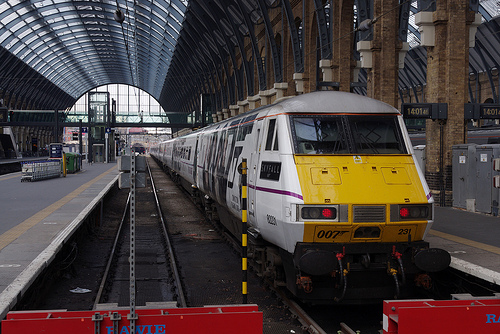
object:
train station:
[1, 1, 498, 332]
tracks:
[90, 156, 189, 311]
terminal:
[1, 127, 125, 317]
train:
[148, 91, 452, 305]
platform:
[1, 161, 119, 314]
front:
[282, 89, 436, 254]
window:
[289, 114, 353, 158]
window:
[347, 113, 409, 157]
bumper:
[2, 302, 265, 333]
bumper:
[383, 292, 499, 333]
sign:
[402, 105, 432, 118]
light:
[321, 207, 332, 219]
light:
[399, 206, 410, 218]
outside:
[62, 84, 172, 157]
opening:
[63, 85, 173, 155]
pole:
[241, 160, 249, 303]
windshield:
[288, 112, 408, 154]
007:
[316, 230, 341, 240]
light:
[113, 9, 126, 22]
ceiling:
[1, 0, 424, 122]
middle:
[1, 0, 190, 102]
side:
[147, 107, 306, 256]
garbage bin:
[64, 151, 74, 173]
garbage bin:
[76, 153, 81, 172]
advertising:
[192, 114, 257, 211]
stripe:
[1, 163, 118, 249]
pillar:
[426, 0, 466, 207]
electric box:
[451, 143, 473, 212]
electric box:
[476, 145, 499, 214]